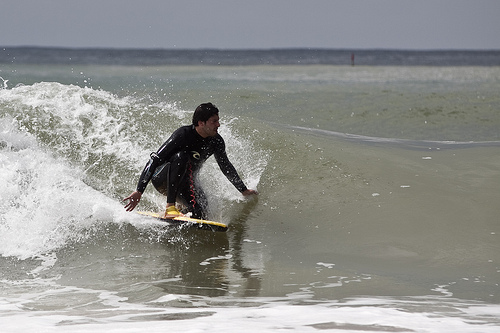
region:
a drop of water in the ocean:
[51, 236, 68, 243]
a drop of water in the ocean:
[33, 246, 40, 253]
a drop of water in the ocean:
[7, 230, 17, 238]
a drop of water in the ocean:
[26, 199, 30, 205]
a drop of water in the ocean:
[92, 216, 111, 225]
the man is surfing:
[123, 58, 251, 278]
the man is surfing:
[134, 63, 263, 265]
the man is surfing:
[108, 60, 285, 275]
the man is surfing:
[113, 62, 265, 252]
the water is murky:
[300, 151, 418, 233]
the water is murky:
[291, 153, 437, 268]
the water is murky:
[283, 168, 430, 286]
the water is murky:
[300, 163, 427, 268]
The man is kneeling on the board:
[124, 91, 276, 253]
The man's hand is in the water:
[218, 141, 278, 208]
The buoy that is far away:
[344, 44, 360, 71]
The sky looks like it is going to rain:
[1, 1, 498, 48]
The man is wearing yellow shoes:
[155, 193, 195, 225]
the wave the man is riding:
[6, 69, 498, 218]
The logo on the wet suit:
[188, 142, 210, 163]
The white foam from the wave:
[8, 82, 113, 129]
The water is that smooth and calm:
[316, 132, 496, 272]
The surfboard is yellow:
[139, 203, 234, 243]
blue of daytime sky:
[1, 0, 497, 45]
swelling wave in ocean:
[3, 79, 498, 270]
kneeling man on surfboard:
[124, 101, 256, 230]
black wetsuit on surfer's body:
[138, 122, 256, 212]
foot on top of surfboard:
[141, 204, 226, 233]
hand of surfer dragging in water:
[213, 142, 259, 202]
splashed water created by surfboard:
[0, 145, 189, 260]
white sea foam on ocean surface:
[1, 286, 498, 331]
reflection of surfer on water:
[155, 202, 257, 301]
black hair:
[190, 98, 215, 118]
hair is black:
[191, 98, 218, 120]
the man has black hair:
[191, 100, 226, 138]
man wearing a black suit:
[158, 120, 216, 204]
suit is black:
[157, 125, 208, 213]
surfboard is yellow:
[150, 208, 225, 239]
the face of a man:
[199, 110, 226, 140]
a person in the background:
[347, 48, 359, 64]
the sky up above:
[71, 0, 473, 55]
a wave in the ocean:
[30, 138, 142, 286]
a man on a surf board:
[125, 100, 259, 234]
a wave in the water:
[0, 85, 154, 249]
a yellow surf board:
[138, 203, 234, 233]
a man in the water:
[115, 95, 258, 234]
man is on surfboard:
[124, 100, 264, 219]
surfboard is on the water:
[137, 206, 229, 228]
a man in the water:
[85, 54, 296, 270]